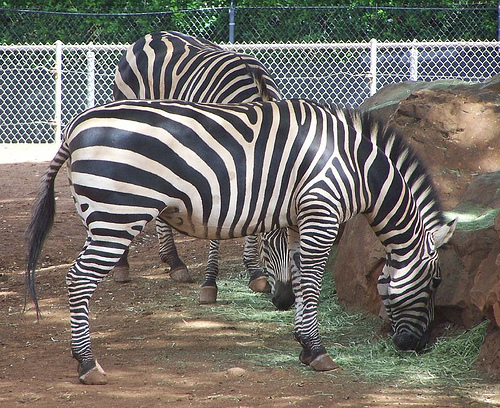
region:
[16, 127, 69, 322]
Long tail on zebra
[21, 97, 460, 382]
Zebra grazing inside of enclosure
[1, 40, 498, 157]
Metal chain link fence of enclosure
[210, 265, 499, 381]
Green hay for zebra grazing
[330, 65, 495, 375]
Rock inside of enclosure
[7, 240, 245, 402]
Bare ground inside enclosure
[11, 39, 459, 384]
Two zebras in an enclosure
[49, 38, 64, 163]
Metal fencepost of chain link fence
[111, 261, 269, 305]
Brown hooves of zebra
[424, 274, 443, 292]
Black eye of zebra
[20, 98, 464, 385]
Black and white zebra grazing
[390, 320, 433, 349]
Black mouth on green grass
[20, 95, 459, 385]
Black and white zebra in front of rock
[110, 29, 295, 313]
Black and white zebra grazing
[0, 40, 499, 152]
White fence behind zebra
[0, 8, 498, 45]
Black fence behind white fence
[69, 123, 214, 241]
Thick black stripe on zebra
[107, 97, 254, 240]
Thick black stripe on zebra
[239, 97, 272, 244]
Thick black stripe on zebra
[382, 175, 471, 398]
the zebra is eating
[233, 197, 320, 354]
the zebra is eating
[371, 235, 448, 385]
the zebra is eating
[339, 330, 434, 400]
green grass on the ground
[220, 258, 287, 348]
green grass on the ground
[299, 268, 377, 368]
green grass on the ground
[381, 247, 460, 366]
This zebra has a rather long face here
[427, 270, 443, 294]
This zebra has a very dark black eye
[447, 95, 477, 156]
There is brown rock that is visible here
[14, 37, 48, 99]
There is a gray fence that is in the background here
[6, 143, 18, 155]
There is a grey cement area that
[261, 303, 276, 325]
There is green grass that is visible here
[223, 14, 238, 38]
There is a blue pole that is visible here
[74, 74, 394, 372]
Jackson Mingus took this photo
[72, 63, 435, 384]
This photo was taken in the continent of Africa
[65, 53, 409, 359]
This photo was taken in the country of South Africa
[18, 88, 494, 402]
This is a zebra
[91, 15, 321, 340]
This is a zebra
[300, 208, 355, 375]
Leg of a zebra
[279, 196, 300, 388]
Leg of a zebra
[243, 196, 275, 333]
Leg of a zebra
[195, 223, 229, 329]
Leg of a zebra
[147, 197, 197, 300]
Leg of a zebra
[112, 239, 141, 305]
Leg of a zebra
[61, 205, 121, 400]
Leg of a zebra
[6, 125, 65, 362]
Tail of a zebra